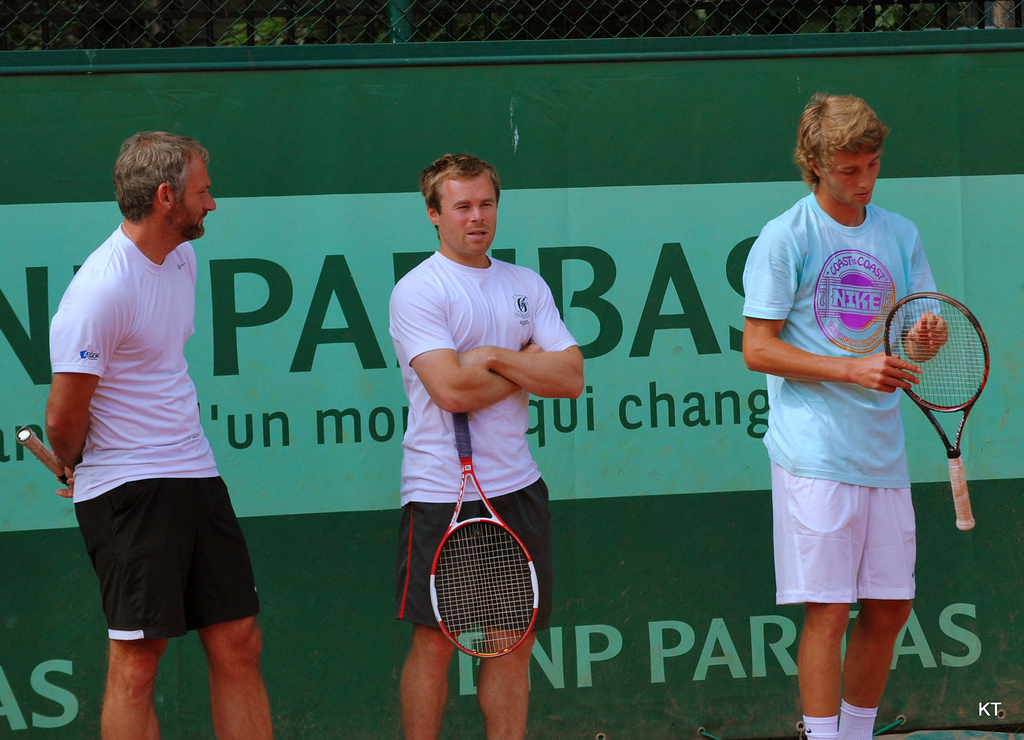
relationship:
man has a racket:
[385, 156, 583, 739] [426, 414, 540, 657]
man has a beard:
[385, 156, 583, 739] [165, 189, 206, 240]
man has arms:
[385, 156, 583, 739] [400, 303, 582, 409]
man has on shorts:
[385, 156, 583, 739] [75, 479, 259, 645]